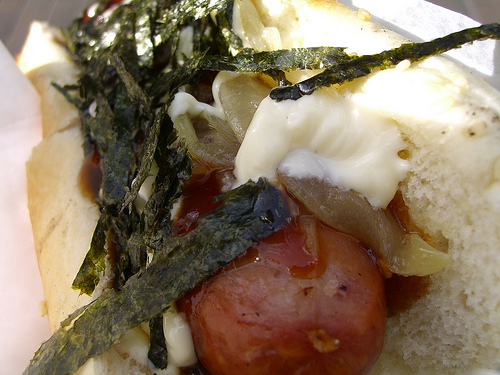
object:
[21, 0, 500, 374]
topping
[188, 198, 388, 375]
hotdog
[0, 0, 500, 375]
bun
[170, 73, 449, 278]
onions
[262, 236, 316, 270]
sauce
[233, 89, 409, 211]
mayo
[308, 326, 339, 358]
tip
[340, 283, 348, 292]
speck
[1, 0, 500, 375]
wrapper